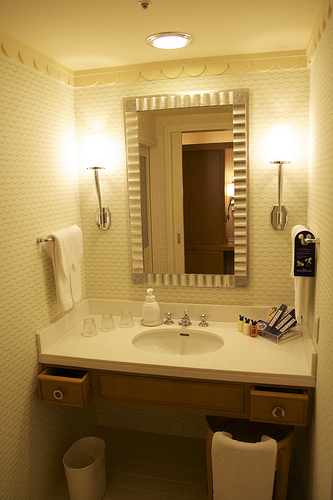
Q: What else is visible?
A: A sink.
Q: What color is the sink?
A: White.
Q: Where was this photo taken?
A: In a bathroom.